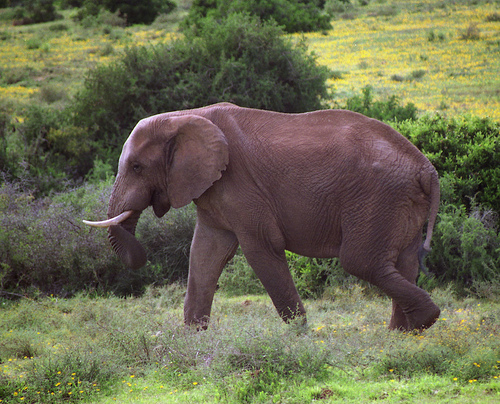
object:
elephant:
[82, 102, 441, 336]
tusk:
[82, 211, 133, 228]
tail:
[420, 163, 440, 276]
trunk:
[106, 187, 147, 270]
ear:
[164, 115, 230, 209]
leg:
[234, 222, 307, 325]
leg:
[183, 219, 239, 334]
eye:
[131, 163, 141, 171]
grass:
[1, 0, 499, 402]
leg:
[339, 215, 430, 319]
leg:
[386, 229, 422, 331]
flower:
[130, 374, 135, 378]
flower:
[71, 372, 77, 377]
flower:
[57, 371, 62, 376]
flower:
[389, 368, 394, 372]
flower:
[453, 377, 458, 382]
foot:
[178, 324, 208, 332]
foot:
[280, 322, 310, 336]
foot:
[402, 300, 441, 334]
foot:
[387, 323, 408, 332]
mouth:
[148, 188, 171, 218]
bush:
[1, 10, 210, 93]